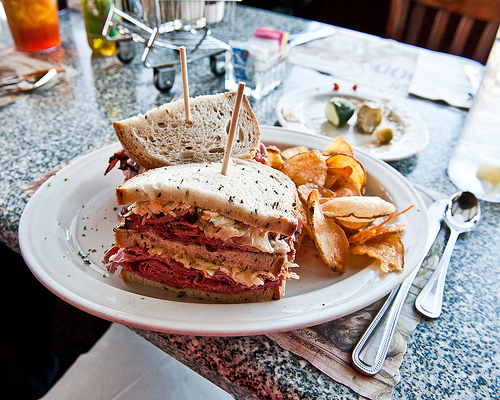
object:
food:
[88, 81, 403, 304]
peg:
[219, 81, 246, 173]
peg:
[176, 46, 192, 123]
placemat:
[268, 184, 448, 399]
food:
[326, 96, 393, 146]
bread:
[115, 154, 305, 236]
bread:
[113, 247, 288, 291]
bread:
[121, 270, 286, 302]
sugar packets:
[255, 26, 286, 47]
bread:
[113, 88, 261, 168]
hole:
[154, 121, 173, 131]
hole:
[168, 120, 179, 130]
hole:
[178, 150, 197, 160]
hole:
[206, 144, 226, 156]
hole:
[235, 126, 248, 144]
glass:
[445, 25, 498, 203]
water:
[99, 46, 111, 53]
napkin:
[407, 48, 481, 109]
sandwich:
[101, 156, 307, 304]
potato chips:
[365, 235, 409, 276]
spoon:
[413, 189, 482, 319]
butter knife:
[350, 197, 450, 377]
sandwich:
[106, 90, 262, 180]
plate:
[276, 85, 430, 162]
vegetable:
[325, 97, 355, 127]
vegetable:
[357, 100, 386, 131]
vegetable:
[373, 126, 393, 147]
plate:
[47, 93, 396, 340]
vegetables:
[193, 98, 364, 249]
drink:
[31, 0, 66, 52]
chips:
[321, 193, 397, 215]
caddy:
[223, 43, 289, 102]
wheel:
[153, 62, 176, 93]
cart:
[104, 7, 231, 94]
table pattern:
[0, 3, 497, 397]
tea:
[77, 6, 112, 52]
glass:
[27, 33, 44, 54]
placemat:
[284, 17, 361, 75]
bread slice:
[111, 222, 289, 275]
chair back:
[385, 2, 499, 66]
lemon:
[476, 163, 498, 185]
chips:
[353, 236, 406, 273]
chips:
[254, 145, 283, 168]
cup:
[0, 0, 61, 52]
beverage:
[22, 9, 54, 35]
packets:
[233, 23, 287, 67]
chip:
[307, 196, 353, 274]